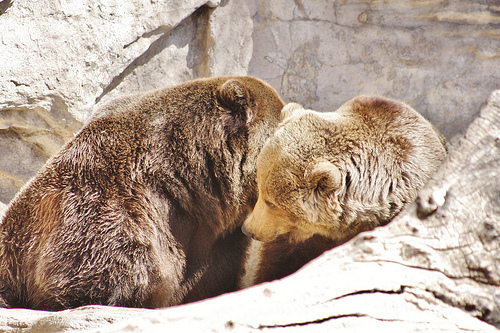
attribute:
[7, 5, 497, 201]
wall — rocky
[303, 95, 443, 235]
fur — ruffled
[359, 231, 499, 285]
area — cracked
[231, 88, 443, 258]
bear — brown, baby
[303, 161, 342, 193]
ear — round, brown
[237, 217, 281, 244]
nose — black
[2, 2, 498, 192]
rock — hard